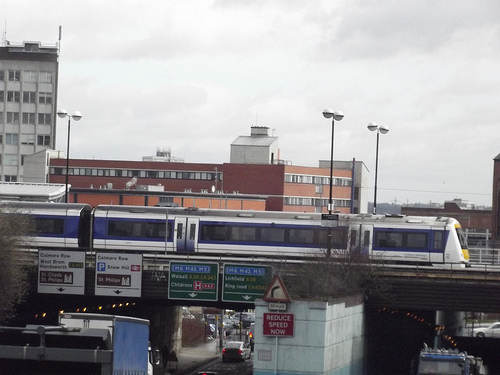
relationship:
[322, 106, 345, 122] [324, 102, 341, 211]
lights on post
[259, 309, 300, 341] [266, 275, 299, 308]
sign says curve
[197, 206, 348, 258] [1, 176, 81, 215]
train at station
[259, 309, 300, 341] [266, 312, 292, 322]
sign says reduce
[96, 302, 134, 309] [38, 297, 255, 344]
lights in tunnel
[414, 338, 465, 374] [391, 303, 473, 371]
truck in tunnel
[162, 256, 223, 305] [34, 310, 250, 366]
signs above traffic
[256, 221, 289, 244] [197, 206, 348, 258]
window of train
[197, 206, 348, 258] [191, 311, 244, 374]
train over freeway